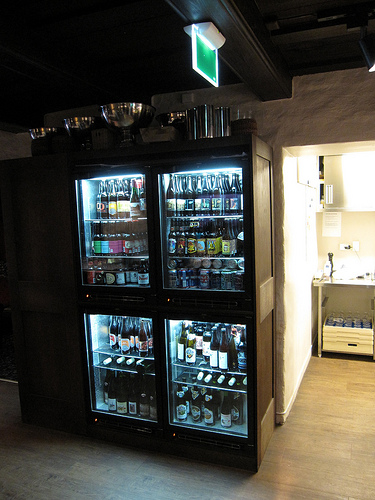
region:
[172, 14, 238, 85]
green sign over cooler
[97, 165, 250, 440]
liquor bottles in cooler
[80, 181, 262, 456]
cooler has black door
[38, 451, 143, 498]
light brown wooden floor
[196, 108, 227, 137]
metal pot on cooler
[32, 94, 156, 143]
three round pots on cooler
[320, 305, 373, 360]
brown drawer under counter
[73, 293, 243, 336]
small lights on doors of cooler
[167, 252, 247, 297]
aluminum cans in cooler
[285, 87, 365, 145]
brown wall over doorway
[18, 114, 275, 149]
bowls sitting on top of a refridgerator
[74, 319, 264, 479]
beer bottles displayed on the bottom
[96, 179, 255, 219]
beer bottles sitting on the top shelf of the fridge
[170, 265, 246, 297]
beer cans stacked on the bottom shelf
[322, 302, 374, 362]
a wooden create filled with items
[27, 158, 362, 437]
beer fridgerator standing near a doorway.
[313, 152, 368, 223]
a silver cabinet hanging above a counter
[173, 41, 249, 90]
signage hanging on the ceiling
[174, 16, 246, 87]
signaged hanging above the refridgerator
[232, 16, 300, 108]
beams created across the ceiling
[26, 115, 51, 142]
this is a bowl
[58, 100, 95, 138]
this is a bowl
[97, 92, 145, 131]
this is a bowl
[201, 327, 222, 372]
this is a bottle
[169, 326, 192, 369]
this is a bottle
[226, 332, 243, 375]
this is a bottle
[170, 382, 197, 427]
this is a bottle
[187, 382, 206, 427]
this is a bottle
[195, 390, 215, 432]
this is a bottle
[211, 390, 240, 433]
this is a bottle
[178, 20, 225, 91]
green light on ceiling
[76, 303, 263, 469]
freezers with alcoholic beverages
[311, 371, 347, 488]
a wooden finished floor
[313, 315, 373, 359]
soda cans on a shelf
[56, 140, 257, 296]
freezers on top of other freezers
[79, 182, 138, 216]
bottles of beer in freezer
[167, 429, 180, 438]
orange light on freezer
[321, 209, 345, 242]
piece of paper on wall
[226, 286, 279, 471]
wooden door on side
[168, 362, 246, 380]
shelf in the freezer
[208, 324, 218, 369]
bottle with white label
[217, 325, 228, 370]
bottle with white label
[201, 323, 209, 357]
bottle with white label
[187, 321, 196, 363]
bottle with white label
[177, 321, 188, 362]
bottle with white label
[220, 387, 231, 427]
bottle with white label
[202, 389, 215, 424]
bottle with white label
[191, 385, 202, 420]
bottle with white label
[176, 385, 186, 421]
bottle with white label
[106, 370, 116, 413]
bottle with white label